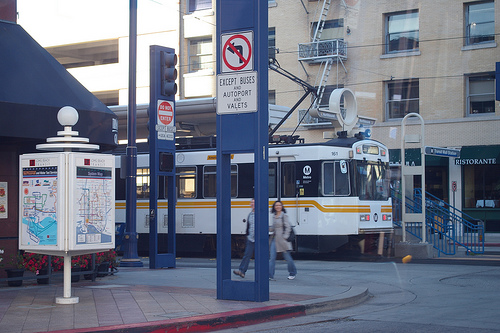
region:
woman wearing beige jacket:
[267, 195, 306, 277]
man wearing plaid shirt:
[239, 195, 265, 281]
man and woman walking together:
[236, 184, 295, 286]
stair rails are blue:
[392, 161, 483, 252]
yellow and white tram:
[118, 125, 385, 255]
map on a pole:
[20, 145, 125, 262]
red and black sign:
[215, 26, 267, 85]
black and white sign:
[215, 59, 249, 117]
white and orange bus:
[136, 143, 384, 255]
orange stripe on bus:
[102, 175, 380, 232]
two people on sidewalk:
[247, 198, 297, 282]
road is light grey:
[401, 268, 446, 332]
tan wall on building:
[417, 54, 469, 137]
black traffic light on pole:
[158, 46, 189, 119]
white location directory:
[22, 132, 145, 283]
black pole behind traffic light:
[122, 16, 146, 193]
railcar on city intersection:
[12, 23, 489, 320]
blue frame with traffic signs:
[213, 10, 270, 302]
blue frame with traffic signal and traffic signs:
[147, 43, 177, 268]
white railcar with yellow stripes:
[107, 140, 394, 257]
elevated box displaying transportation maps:
[20, 105, 115, 305]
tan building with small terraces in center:
[120, 8, 491, 257]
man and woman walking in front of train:
[230, 199, 306, 284]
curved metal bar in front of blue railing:
[391, 112, 497, 254]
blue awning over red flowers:
[5, 14, 120, 286]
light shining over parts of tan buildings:
[22, 6, 212, 99]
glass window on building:
[466, 1, 496, 21]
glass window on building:
[466, 21, 491, 40]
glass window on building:
[468, 74, 493, 92]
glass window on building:
[468, 94, 493, 111]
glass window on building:
[384, 13, 419, 29]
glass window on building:
[386, 30, 418, 53]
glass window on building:
[386, 81, 419, 97]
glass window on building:
[386, 100, 418, 117]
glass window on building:
[188, 37, 213, 53]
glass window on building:
[188, 53, 213, 68]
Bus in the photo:
[170, 134, 390, 252]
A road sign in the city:
[205, 14, 279, 225]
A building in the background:
[375, 14, 498, 117]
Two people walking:
[232, 180, 309, 281]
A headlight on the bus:
[347, 202, 411, 237]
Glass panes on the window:
[384, 7, 434, 61]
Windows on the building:
[365, 10, 485, 123]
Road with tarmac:
[362, 265, 459, 330]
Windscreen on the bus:
[358, 160, 394, 196]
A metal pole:
[117, 82, 152, 223]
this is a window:
[384, 77, 424, 119]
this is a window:
[463, 73, 496, 117]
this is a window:
[383, 10, 420, 55]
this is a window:
[465, 5, 497, 48]